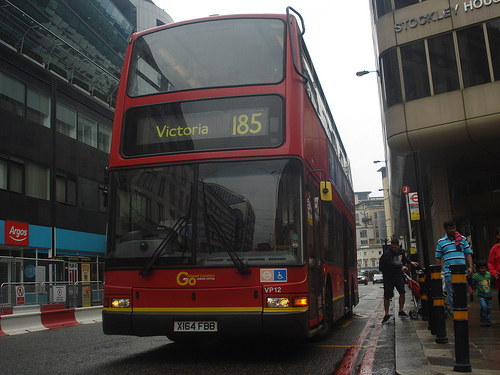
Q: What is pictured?
A: A bus.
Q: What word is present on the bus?
A: Victoria.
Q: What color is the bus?
A: Red.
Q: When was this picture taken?
A: During the day.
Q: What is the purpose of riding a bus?
A: Transportation.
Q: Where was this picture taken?
A: On the street.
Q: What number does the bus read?
A: 185.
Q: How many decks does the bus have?
A: Two.